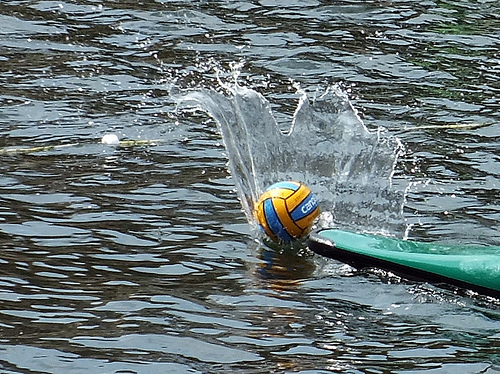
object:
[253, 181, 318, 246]
ball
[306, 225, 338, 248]
tip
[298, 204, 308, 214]
letters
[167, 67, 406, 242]
splash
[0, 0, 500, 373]
water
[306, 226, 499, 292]
object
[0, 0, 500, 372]
ripples